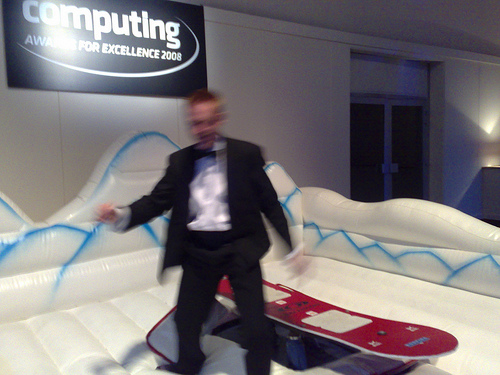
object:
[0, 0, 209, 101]
sign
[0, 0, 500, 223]
wall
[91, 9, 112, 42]
letter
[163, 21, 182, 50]
letter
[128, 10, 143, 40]
letter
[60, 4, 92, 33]
letter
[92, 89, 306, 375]
man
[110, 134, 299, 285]
jacket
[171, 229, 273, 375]
pants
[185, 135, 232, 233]
shirt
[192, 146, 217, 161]
tie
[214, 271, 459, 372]
snowboard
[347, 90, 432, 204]
door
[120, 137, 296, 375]
tux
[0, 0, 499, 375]
event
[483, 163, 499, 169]
light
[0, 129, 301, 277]
mountain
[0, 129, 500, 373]
inflatable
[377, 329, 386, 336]
bolt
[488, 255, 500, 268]
line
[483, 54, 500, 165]
corner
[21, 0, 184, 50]
computing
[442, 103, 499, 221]
shadow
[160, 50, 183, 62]
2008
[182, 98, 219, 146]
face